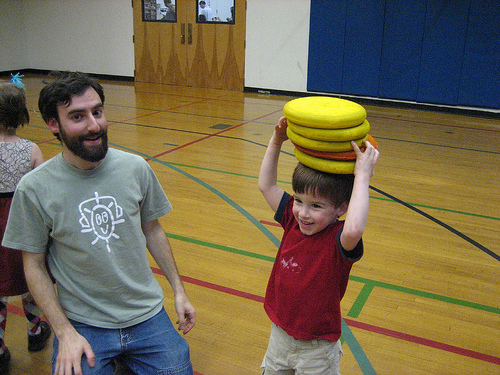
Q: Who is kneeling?
A: A man.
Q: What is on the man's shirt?
A: Sun.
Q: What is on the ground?
A: Lines.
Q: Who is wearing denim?
A: The man.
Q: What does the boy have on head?
A: Frisbees.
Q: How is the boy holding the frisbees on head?
A: With his hands.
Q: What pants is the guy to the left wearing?
A: Jeans.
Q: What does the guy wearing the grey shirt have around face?
A: A beard.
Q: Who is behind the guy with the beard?
A: A little girl.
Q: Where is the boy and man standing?
A: In the gym.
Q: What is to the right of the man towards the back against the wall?
A: The doors.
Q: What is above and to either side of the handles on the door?
A: The windows.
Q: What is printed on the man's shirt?
A: A design.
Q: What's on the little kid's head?
A: A stack of flat discs.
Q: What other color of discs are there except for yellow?
A: Red.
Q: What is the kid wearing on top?
A: A red t shirt.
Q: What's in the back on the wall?
A: Blue pads.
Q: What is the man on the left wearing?
A: Blue jeans.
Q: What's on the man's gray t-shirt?
A: An image.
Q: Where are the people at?
A: Gym.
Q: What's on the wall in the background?
A: Dark blue padded mats.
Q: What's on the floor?
A: Different colors are painted.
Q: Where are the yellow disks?
A: On the head of the child.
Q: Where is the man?
A: Next to the boy.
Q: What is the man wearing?
A: A gray shirt.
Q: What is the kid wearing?
A: A red shirt.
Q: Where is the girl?
A: Behind the man.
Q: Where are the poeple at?
A: The gym.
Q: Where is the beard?
A: On the man.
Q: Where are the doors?
A: In the distance near the padded wall.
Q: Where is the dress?
A: On the girl.